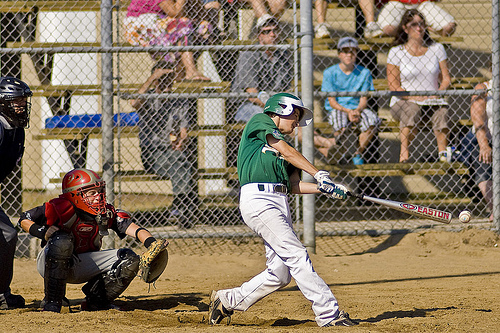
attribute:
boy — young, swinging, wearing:
[173, 81, 353, 326]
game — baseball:
[26, 37, 458, 317]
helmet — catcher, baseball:
[26, 154, 132, 238]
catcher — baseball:
[4, 138, 196, 331]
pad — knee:
[65, 252, 156, 318]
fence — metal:
[79, 27, 210, 222]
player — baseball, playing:
[213, 48, 396, 333]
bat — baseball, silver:
[286, 164, 472, 255]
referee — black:
[0, 73, 72, 295]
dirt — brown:
[388, 266, 446, 312]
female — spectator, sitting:
[356, 9, 453, 167]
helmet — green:
[273, 81, 309, 117]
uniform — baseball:
[232, 78, 344, 212]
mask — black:
[76, 179, 94, 211]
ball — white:
[446, 196, 477, 239]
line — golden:
[168, 273, 212, 302]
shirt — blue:
[316, 59, 375, 117]